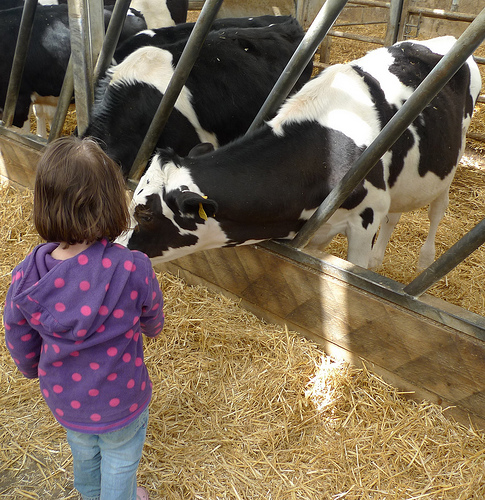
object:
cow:
[112, 35, 482, 272]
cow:
[78, 14, 315, 186]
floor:
[0, 0, 484, 500]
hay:
[0, 11, 484, 498]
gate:
[0, 1, 484, 335]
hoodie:
[2, 237, 164, 435]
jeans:
[63, 406, 150, 500]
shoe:
[135, 486, 150, 498]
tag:
[196, 202, 209, 223]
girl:
[2, 132, 164, 500]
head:
[113, 141, 216, 268]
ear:
[172, 189, 219, 223]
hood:
[13, 241, 137, 343]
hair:
[33, 133, 141, 244]